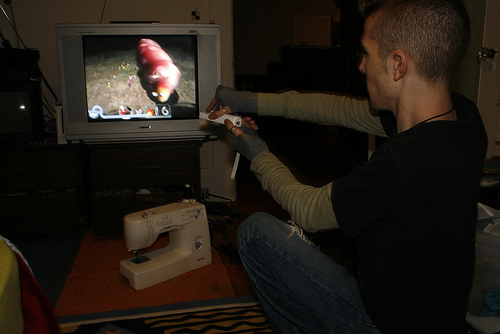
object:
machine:
[114, 200, 212, 292]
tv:
[58, 23, 224, 144]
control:
[197, 111, 242, 129]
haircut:
[367, 2, 466, 87]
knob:
[19, 104, 26, 112]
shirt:
[330, 86, 473, 334]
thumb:
[221, 119, 243, 143]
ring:
[228, 124, 236, 132]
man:
[206, 2, 496, 333]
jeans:
[236, 213, 380, 334]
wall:
[2, 0, 233, 205]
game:
[83, 33, 201, 119]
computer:
[290, 11, 333, 51]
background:
[0, 0, 499, 334]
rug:
[49, 220, 234, 321]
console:
[53, 104, 73, 144]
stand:
[87, 139, 203, 249]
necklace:
[392, 105, 458, 140]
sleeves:
[244, 147, 332, 234]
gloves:
[212, 85, 268, 116]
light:
[12, 98, 36, 126]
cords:
[38, 69, 58, 103]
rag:
[467, 314, 500, 333]